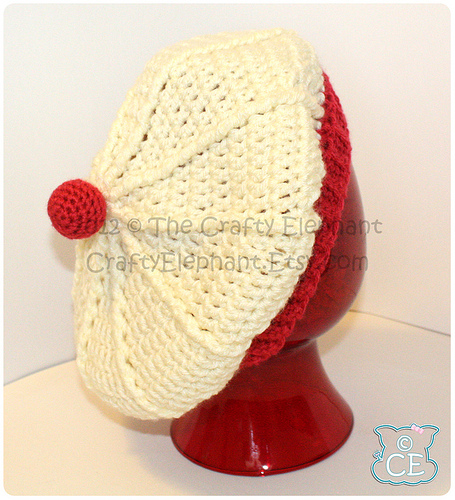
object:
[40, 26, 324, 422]
cap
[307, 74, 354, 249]
yarn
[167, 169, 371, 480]
model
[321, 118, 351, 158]
red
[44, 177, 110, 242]
pom pom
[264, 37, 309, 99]
crochet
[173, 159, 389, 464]
mannequin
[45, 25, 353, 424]
hat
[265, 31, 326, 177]
crocheted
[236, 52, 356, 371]
border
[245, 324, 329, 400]
glare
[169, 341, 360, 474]
neck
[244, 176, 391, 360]
head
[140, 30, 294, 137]
clit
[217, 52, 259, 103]
row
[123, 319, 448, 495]
shadow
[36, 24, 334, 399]
cover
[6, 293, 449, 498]
counter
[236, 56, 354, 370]
trim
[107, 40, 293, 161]
knitted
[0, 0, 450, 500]
photo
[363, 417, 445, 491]
watermark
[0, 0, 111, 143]
wall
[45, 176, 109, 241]
ball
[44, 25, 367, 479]
display